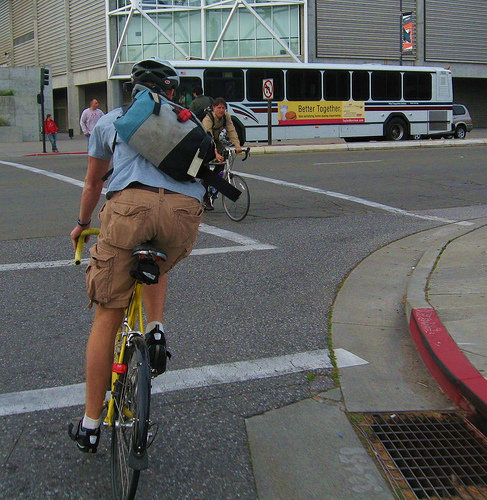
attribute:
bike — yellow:
[69, 217, 178, 500]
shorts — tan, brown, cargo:
[83, 177, 204, 309]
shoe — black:
[64, 414, 102, 457]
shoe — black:
[137, 323, 173, 381]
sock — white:
[80, 413, 103, 432]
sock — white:
[145, 318, 168, 337]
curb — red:
[405, 302, 487, 419]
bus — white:
[154, 57, 456, 150]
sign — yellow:
[273, 100, 368, 129]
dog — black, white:
[401, 26, 412, 45]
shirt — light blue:
[80, 102, 208, 206]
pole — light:
[37, 63, 49, 153]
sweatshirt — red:
[43, 116, 57, 133]